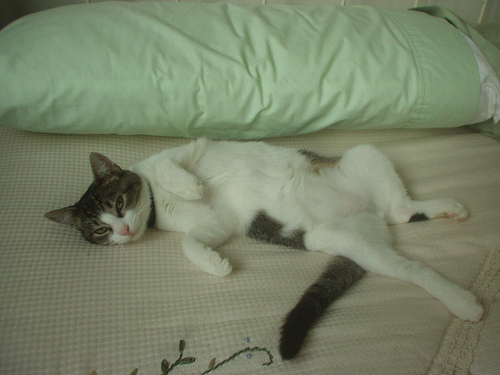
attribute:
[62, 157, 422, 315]
cat — brown, white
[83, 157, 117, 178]
ear — brown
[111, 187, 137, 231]
eye — beautiful, green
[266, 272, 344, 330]
tail — long, black, brown, gray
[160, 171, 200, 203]
paw — white, back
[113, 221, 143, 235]
nose — soft, pink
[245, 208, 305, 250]
spot — black, brown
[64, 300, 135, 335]
blanket — white, pink, patterned, stitched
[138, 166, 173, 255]
collar — black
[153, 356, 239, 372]
stitch — green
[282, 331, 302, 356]
tip — black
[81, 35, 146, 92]
pillow — green, wrinkled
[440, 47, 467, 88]
case — green